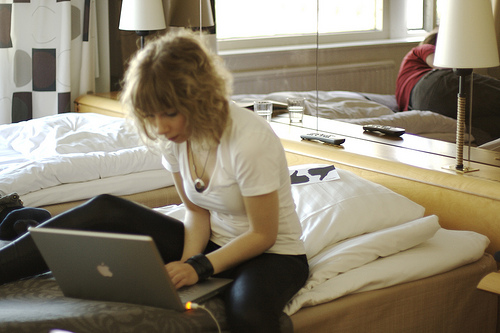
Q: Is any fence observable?
A: No, there are no fences.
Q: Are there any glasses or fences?
A: No, there are no fences or glasses.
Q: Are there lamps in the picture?
A: Yes, there is a lamp.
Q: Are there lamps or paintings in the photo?
A: Yes, there is a lamp.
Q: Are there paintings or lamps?
A: Yes, there is a lamp.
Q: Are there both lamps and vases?
A: No, there is a lamp but no vases.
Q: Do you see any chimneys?
A: No, there are no chimneys.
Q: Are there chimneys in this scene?
A: No, there are no chimneys.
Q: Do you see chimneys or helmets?
A: No, there are no chimneys or helmets.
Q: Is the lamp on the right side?
A: Yes, the lamp is on the right of the image.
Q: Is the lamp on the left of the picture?
A: No, the lamp is on the right of the image.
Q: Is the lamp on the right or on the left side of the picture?
A: The lamp is on the right of the image.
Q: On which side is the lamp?
A: The lamp is on the right of the image.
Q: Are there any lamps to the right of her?
A: Yes, there is a lamp to the right of the girl.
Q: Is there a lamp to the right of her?
A: Yes, there is a lamp to the right of the girl.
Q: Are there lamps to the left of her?
A: No, the lamp is to the right of the girl.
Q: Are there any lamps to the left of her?
A: No, the lamp is to the right of the girl.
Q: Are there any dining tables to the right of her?
A: No, there is a lamp to the right of the girl.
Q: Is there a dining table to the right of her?
A: No, there is a lamp to the right of the girl.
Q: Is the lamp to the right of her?
A: Yes, the lamp is to the right of the girl.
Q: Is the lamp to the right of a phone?
A: No, the lamp is to the right of the girl.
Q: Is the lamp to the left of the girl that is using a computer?
A: No, the lamp is to the right of the girl.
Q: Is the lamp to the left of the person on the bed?
A: No, the lamp is to the right of the girl.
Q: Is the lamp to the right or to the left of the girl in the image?
A: The lamp is to the right of the girl.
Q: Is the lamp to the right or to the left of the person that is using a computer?
A: The lamp is to the right of the girl.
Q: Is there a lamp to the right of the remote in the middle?
A: Yes, there is a lamp to the right of the remote.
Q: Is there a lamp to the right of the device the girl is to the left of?
A: Yes, there is a lamp to the right of the remote.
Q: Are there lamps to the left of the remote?
A: No, the lamp is to the right of the remote.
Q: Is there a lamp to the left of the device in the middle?
A: No, the lamp is to the right of the remote.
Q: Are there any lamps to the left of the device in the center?
A: No, the lamp is to the right of the remote.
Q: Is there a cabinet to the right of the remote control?
A: No, there is a lamp to the right of the remote control.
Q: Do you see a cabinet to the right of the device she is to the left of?
A: No, there is a lamp to the right of the remote control.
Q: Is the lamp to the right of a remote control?
A: Yes, the lamp is to the right of a remote control.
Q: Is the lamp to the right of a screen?
A: No, the lamp is to the right of a remote control.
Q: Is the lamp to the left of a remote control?
A: No, the lamp is to the right of a remote control.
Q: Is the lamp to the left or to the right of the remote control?
A: The lamp is to the right of the remote control.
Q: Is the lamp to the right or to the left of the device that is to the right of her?
A: The lamp is to the right of the remote control.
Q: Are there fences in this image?
A: No, there are no fences.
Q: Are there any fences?
A: No, there are no fences.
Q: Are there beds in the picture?
A: Yes, there is a bed.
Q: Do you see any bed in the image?
A: Yes, there is a bed.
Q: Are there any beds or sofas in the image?
A: Yes, there is a bed.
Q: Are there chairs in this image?
A: No, there are no chairs.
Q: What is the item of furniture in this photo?
A: The piece of furniture is a bed.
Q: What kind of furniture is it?
A: The piece of furniture is a bed.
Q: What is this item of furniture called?
A: This is a bed.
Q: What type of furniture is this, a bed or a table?
A: This is a bed.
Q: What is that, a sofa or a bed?
A: That is a bed.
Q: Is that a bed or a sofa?
A: That is a bed.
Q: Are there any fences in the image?
A: No, there are no fences.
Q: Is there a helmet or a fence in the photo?
A: No, there are no fences or helmets.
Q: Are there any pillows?
A: Yes, there is a pillow.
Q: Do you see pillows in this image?
A: Yes, there is a pillow.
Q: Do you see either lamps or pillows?
A: Yes, there is a pillow.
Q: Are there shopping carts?
A: No, there are no shopping carts.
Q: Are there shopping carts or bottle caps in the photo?
A: No, there are no shopping carts or bottle caps.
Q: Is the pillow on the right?
A: Yes, the pillow is on the right of the image.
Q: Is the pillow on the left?
A: No, the pillow is on the right of the image.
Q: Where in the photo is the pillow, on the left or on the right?
A: The pillow is on the right of the image.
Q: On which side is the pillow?
A: The pillow is on the right of the image.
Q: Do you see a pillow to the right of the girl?
A: Yes, there is a pillow to the right of the girl.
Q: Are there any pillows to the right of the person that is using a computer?
A: Yes, there is a pillow to the right of the girl.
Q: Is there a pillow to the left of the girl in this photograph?
A: No, the pillow is to the right of the girl.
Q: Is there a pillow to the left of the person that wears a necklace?
A: No, the pillow is to the right of the girl.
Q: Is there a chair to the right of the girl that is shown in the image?
A: No, there is a pillow to the right of the girl.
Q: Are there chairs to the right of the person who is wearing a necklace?
A: No, there is a pillow to the right of the girl.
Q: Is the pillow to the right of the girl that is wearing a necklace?
A: Yes, the pillow is to the right of the girl.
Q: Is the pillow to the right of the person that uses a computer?
A: Yes, the pillow is to the right of the girl.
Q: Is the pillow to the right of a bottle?
A: No, the pillow is to the right of the girl.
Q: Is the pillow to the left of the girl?
A: No, the pillow is to the right of the girl.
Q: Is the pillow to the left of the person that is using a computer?
A: No, the pillow is to the right of the girl.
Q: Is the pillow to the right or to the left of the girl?
A: The pillow is to the right of the girl.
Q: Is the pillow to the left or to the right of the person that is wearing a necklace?
A: The pillow is to the right of the girl.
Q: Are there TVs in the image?
A: No, there are no tvs.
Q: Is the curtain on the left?
A: Yes, the curtain is on the left of the image.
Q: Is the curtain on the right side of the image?
A: No, the curtain is on the left of the image.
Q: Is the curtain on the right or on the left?
A: The curtain is on the left of the image.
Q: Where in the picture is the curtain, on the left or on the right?
A: The curtain is on the left of the image.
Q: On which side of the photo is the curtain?
A: The curtain is on the left of the image.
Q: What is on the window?
A: The curtain is on the window.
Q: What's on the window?
A: The curtain is on the window.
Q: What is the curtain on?
A: The curtain is on the window.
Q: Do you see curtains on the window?
A: Yes, there is a curtain on the window.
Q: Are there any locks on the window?
A: No, there is a curtain on the window.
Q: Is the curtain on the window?
A: Yes, the curtain is on the window.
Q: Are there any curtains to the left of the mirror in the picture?
A: Yes, there is a curtain to the left of the mirror.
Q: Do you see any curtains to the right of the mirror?
A: No, the curtain is to the left of the mirror.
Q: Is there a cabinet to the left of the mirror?
A: No, there is a curtain to the left of the mirror.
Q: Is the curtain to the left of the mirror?
A: Yes, the curtain is to the left of the mirror.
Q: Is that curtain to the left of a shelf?
A: No, the curtain is to the left of the mirror.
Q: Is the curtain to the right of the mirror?
A: No, the curtain is to the left of the mirror.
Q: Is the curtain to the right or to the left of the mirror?
A: The curtain is to the left of the mirror.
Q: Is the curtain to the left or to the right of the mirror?
A: The curtain is to the left of the mirror.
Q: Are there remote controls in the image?
A: Yes, there is a remote control.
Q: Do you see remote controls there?
A: Yes, there is a remote control.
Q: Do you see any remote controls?
A: Yes, there is a remote control.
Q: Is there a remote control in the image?
A: Yes, there is a remote control.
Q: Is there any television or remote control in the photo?
A: Yes, there is a remote control.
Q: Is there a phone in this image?
A: No, there are no phones.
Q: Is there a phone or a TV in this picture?
A: No, there are no phones or televisions.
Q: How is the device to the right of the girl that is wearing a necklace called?
A: The device is a remote control.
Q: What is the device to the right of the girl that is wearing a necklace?
A: The device is a remote control.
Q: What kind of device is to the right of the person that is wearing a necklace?
A: The device is a remote control.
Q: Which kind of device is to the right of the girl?
A: The device is a remote control.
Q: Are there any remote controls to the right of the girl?
A: Yes, there is a remote control to the right of the girl.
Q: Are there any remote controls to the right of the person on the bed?
A: Yes, there is a remote control to the right of the girl.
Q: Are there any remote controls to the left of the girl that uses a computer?
A: No, the remote control is to the right of the girl.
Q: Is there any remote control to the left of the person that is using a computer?
A: No, the remote control is to the right of the girl.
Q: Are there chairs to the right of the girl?
A: No, there is a remote control to the right of the girl.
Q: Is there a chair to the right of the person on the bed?
A: No, there is a remote control to the right of the girl.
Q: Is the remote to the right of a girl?
A: Yes, the remote is to the right of a girl.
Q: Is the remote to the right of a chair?
A: No, the remote is to the right of a girl.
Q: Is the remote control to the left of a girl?
A: No, the remote control is to the right of a girl.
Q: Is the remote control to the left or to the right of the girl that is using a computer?
A: The remote control is to the right of the girl.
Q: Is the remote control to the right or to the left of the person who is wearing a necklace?
A: The remote control is to the right of the girl.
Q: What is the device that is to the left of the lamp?
A: The device is a remote control.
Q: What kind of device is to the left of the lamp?
A: The device is a remote control.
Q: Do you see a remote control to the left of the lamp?
A: Yes, there is a remote control to the left of the lamp.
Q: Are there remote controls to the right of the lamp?
A: No, the remote control is to the left of the lamp.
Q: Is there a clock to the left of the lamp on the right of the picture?
A: No, there is a remote control to the left of the lamp.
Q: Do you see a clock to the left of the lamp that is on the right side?
A: No, there is a remote control to the left of the lamp.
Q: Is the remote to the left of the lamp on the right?
A: Yes, the remote is to the left of the lamp.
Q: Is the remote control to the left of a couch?
A: No, the remote control is to the left of the lamp.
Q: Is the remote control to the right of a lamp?
A: No, the remote control is to the left of a lamp.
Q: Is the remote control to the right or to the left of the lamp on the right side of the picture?
A: The remote control is to the left of the lamp.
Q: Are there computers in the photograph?
A: Yes, there is a computer.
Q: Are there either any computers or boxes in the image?
A: Yes, there is a computer.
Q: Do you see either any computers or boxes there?
A: Yes, there is a computer.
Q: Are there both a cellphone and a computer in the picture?
A: No, there is a computer but no cell phones.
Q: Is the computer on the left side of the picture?
A: Yes, the computer is on the left of the image.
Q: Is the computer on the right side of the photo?
A: No, the computer is on the left of the image.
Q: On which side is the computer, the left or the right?
A: The computer is on the left of the image.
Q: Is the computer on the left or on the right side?
A: The computer is on the left of the image.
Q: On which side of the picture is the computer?
A: The computer is on the left of the image.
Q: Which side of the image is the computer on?
A: The computer is on the left of the image.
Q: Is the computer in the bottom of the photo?
A: Yes, the computer is in the bottom of the image.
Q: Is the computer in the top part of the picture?
A: No, the computer is in the bottom of the image.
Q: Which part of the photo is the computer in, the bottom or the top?
A: The computer is in the bottom of the image.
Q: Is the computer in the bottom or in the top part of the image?
A: The computer is in the bottom of the image.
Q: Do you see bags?
A: No, there are no bags.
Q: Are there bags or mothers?
A: No, there are no bags or mothers.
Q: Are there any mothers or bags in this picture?
A: No, there are no bags or mothers.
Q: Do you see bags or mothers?
A: No, there are no bags or mothers.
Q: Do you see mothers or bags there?
A: No, there are no bags or mothers.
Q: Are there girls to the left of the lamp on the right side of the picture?
A: Yes, there is a girl to the left of the lamp.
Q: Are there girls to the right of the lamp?
A: No, the girl is to the left of the lamp.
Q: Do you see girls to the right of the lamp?
A: No, the girl is to the left of the lamp.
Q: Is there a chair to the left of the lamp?
A: No, there is a girl to the left of the lamp.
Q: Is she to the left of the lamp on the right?
A: Yes, the girl is to the left of the lamp.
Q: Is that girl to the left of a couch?
A: No, the girl is to the left of the lamp.